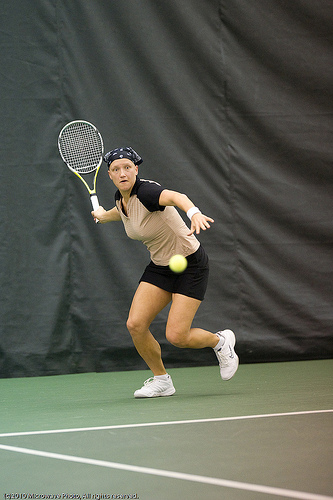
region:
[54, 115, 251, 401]
A woman playing tennis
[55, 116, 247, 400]
A woman playing tennis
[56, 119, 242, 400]
A woman playing tennis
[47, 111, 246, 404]
woman is playing tennis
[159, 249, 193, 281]
a green ball in the air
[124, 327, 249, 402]
a pair of white shoes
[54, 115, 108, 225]
the racket is white and yellow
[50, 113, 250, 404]
tennis player hits a ball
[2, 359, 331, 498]
tennis court is green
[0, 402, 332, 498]
white lines on tennis court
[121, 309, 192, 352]
knees are bend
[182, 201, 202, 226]
a white wristband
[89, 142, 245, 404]
woman has a black skirt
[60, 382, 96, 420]
floor is smooth green in color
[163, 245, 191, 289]
baseball is yellow grreen in color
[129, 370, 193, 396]
shoes are white in color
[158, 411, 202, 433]
floor has white stripes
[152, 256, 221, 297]
short is black in color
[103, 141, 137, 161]
head scarf is black in color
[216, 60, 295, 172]
wall i black in color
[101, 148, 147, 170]
girl has black bandanna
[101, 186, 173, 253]
brown and black shirt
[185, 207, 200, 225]
girl has white wristband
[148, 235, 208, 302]
girl has black shorts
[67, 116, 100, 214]
yellow and black racket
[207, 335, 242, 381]
girl has white shoes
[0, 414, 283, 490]
white lines on court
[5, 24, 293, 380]
grey tarp on wall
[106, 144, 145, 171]
black and white bandanna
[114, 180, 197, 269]
black and brown shirt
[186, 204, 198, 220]
girl has white wristband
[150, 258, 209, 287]
girl has black shorts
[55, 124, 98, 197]
yellow and grey racket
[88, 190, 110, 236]
racket has white handle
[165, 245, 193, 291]
yellow ball in air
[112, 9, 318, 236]
grey tarp behind woman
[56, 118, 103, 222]
racket is in the air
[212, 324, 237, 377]
shoe is off the ground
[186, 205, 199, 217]
wrist band is on ladies wrist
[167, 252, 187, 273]
ball is in the air